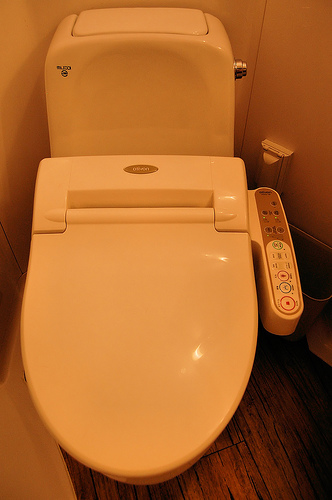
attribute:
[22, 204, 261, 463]
lid — white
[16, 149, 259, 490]
seat — closed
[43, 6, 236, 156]
toilet tank — white 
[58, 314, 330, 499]
floor — wooden 